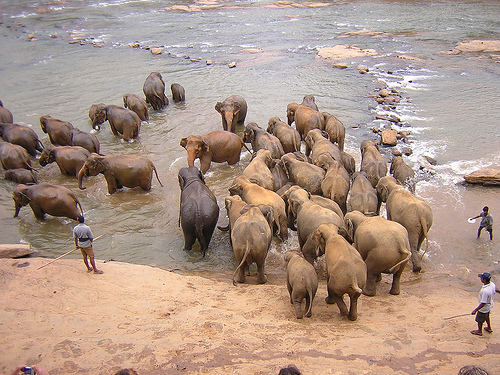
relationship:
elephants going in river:
[2, 68, 431, 327] [0, 0, 499, 295]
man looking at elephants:
[467, 269, 492, 333] [2, 68, 431, 327]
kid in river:
[467, 204, 493, 239] [0, 0, 499, 295]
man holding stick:
[70, 214, 110, 270] [52, 225, 110, 257]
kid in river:
[470, 206, 493, 241] [118, 208, 148, 254]